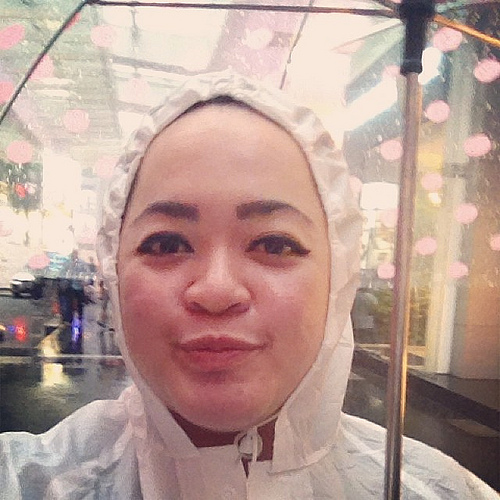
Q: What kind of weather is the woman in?
A: Rain.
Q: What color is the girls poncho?
A: White.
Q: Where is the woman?
A: Shopping center.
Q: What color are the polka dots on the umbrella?
A: Pink.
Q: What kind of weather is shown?
A: Rain.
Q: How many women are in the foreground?
A: One.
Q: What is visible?
A: Woman's face.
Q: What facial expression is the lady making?
A: Smiling.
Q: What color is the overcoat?
A: White.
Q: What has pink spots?
A: Umbrella.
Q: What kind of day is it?
A: Rainy.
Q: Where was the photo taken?
A: Inside a place.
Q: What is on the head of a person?
A: A white hood.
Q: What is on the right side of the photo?
A: White wall.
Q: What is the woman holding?
A: Umbrella.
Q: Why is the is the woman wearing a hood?
A: To keep dry.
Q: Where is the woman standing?
A: On the street.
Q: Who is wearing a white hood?
A: A woman.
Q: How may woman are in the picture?
A: One.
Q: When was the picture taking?
A: The evening.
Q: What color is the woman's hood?
A: White.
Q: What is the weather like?
A: Rainy.